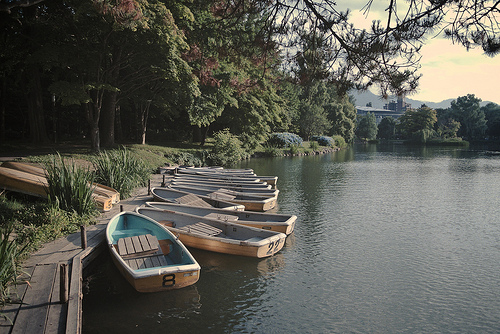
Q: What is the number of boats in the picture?
A: 11.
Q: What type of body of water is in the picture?
A: A lake.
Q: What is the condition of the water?
A: Calm.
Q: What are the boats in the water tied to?
A: A dock.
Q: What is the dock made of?
A: Wood.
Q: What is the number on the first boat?
A: 8.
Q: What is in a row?
A: Boats.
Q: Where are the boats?
A: In the water?.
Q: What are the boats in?
A: The lake.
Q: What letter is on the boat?
A: B.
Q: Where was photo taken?
A: At the lake.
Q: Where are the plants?
A: On shore.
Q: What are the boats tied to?
A: Dock.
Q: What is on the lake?
A: Boats.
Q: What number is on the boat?
A: 22.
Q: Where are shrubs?
A: By the lake.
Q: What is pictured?
A: Boats docked.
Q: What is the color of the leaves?
A: Green.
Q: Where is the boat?
A: Water.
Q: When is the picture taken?
A: Daytime.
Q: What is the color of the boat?
A: Brown.